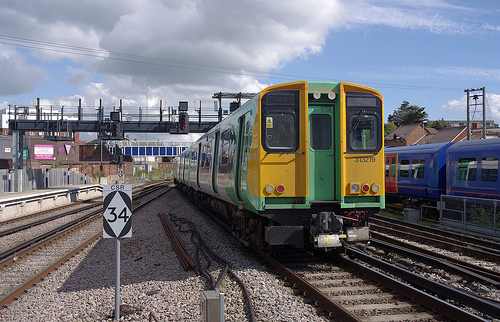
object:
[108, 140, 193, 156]
building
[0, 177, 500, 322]
tracks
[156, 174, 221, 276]
platform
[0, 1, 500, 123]
clouds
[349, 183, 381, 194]
lights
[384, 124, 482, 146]
roofs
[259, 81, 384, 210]
front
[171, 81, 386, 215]
train car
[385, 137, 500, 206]
train car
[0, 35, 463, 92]
power lines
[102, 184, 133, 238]
sign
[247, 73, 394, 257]
snow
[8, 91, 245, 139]
bridge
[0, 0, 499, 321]
background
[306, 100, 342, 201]
door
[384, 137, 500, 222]
train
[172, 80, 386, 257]
train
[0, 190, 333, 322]
pebbles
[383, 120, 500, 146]
homes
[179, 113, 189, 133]
traffic light